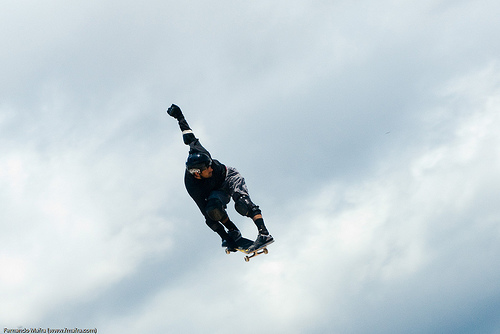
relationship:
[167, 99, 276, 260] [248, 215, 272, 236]
skateboarder wearing sock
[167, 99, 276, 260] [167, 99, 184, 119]
skateboarder wearing glove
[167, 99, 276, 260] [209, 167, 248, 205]
skateboarder wearing pants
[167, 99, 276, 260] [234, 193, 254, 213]
skateboarder wearing knee pad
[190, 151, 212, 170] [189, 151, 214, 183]
helmet on head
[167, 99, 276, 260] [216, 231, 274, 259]
skateboarder on skateboard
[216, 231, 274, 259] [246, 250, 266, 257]
skateboard has arm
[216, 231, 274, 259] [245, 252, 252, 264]
skateboard has wheel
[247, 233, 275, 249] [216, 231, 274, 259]
shoe firmly planted on skateboard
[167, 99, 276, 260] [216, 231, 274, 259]
skateboarder taking a jump on skateboard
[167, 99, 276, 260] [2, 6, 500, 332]
skateboarder in sky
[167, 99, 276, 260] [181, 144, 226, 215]
skateboarder wearing shirt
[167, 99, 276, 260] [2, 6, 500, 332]
skateboarder in front of sky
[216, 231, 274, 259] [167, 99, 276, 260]
skateboard under skateboarder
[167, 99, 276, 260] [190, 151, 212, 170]
skateboarder wearing helmet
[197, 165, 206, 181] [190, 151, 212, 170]
chin strap under helmet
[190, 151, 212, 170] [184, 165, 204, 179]
helmet has writing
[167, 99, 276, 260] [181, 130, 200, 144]
skateboarder wearing elbow pad